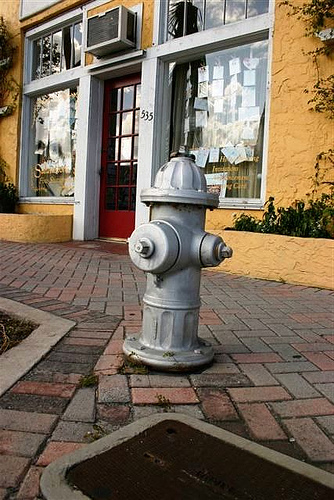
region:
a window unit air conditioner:
[76, 2, 145, 64]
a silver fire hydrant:
[119, 139, 233, 379]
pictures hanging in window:
[156, 45, 265, 197]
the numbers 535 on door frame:
[135, 104, 156, 125]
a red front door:
[93, 67, 146, 245]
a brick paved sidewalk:
[0, 236, 332, 498]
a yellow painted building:
[0, 0, 333, 292]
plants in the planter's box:
[201, 191, 331, 292]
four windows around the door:
[19, 0, 280, 223]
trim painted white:
[14, 0, 274, 243]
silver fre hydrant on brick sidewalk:
[122, 143, 236, 377]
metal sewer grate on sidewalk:
[63, 414, 327, 498]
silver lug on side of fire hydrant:
[122, 217, 182, 273]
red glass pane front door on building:
[94, 75, 144, 245]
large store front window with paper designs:
[162, 32, 266, 200]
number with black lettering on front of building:
[138, 105, 153, 122]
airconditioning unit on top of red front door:
[79, 4, 142, 58]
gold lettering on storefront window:
[199, 143, 269, 194]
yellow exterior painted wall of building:
[276, 31, 333, 287]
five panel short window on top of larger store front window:
[19, 19, 98, 81]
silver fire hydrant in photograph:
[107, 129, 243, 391]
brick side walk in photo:
[15, 250, 276, 447]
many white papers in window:
[176, 90, 277, 197]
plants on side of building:
[211, 187, 332, 270]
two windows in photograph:
[27, 95, 298, 227]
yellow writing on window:
[24, 156, 86, 204]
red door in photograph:
[89, 98, 149, 264]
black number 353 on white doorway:
[125, 100, 172, 140]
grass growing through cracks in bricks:
[91, 330, 200, 418]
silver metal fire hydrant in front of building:
[104, 146, 261, 399]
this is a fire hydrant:
[128, 140, 235, 372]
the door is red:
[57, 28, 192, 298]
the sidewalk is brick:
[239, 293, 297, 388]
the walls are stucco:
[293, 119, 318, 186]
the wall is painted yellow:
[274, 48, 314, 172]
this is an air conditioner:
[81, 9, 156, 47]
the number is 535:
[132, 100, 166, 133]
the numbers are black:
[139, 97, 183, 147]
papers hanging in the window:
[182, 62, 253, 137]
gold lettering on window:
[206, 132, 258, 189]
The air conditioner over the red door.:
[83, 15, 138, 57]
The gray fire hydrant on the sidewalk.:
[135, 134, 239, 370]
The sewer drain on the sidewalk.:
[30, 418, 330, 498]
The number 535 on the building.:
[139, 107, 154, 124]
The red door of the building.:
[99, 78, 135, 236]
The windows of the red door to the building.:
[112, 86, 135, 206]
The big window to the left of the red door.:
[26, 95, 75, 190]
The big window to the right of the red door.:
[169, 63, 264, 192]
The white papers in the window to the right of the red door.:
[183, 52, 266, 173]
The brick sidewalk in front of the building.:
[3, 233, 322, 480]